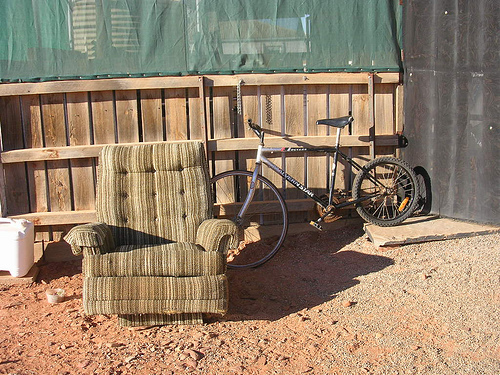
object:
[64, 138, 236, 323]
chair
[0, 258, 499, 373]
ground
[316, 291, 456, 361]
dirt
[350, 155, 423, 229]
wheels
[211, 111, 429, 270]
bicycle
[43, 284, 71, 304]
bowl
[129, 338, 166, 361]
rocks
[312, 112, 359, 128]
seat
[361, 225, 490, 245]
concrete slab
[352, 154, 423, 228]
bicycle tire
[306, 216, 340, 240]
pedal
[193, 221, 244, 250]
arm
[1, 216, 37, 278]
jug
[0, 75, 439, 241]
fence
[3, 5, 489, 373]
yard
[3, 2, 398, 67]
screen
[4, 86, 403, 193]
wall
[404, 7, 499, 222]
tarp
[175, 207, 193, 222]
buttons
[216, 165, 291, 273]
front tyre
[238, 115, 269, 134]
handlebars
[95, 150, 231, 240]
sun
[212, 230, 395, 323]
shadow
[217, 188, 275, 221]
spokes